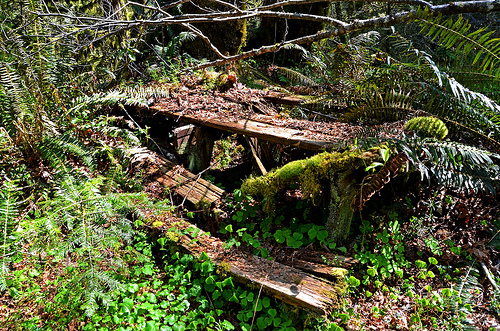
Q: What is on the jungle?
A: Wooden boards.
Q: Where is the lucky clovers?
A: Between wooden boards.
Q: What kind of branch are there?
A: Dry branch of a fallen tree.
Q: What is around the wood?
A: Lucky clovers.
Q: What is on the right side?
A: Dark green bushes.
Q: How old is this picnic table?
A: Very old.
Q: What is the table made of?
A: Wood.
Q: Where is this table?
A: In the woods.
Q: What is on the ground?
A: Green ivy.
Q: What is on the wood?
A: Green moss.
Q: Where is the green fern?
A: On the ground.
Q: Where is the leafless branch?
A: Above the old table.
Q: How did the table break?
A: Age.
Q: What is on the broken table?
A: Branches.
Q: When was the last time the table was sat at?
A: A long time ago.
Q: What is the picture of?
A: A broken down wooden bench.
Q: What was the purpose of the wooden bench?
A: To sit on.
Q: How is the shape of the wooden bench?
A: Broken and torn apart.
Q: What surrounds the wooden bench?
A: Multiple green plants and trees.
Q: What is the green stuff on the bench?
A: Moss.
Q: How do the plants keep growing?
A: With the soil and sunlight.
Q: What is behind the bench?
A: An entrance to a cave.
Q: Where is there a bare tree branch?
A: At the top of the picture.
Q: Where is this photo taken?
A: A forest.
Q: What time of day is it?
A: In the afternoon of the daytime.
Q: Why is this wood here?
A: Discarded.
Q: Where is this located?
A: Forest.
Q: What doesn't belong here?
A: Wood planks.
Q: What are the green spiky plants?
A: Evergreens.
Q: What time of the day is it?
A: Daytime.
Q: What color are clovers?
A: Green.